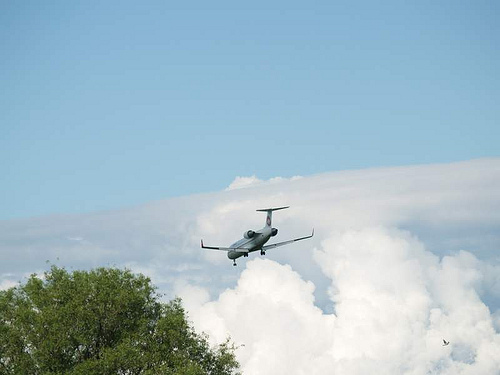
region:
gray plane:
[220, 186, 308, 278]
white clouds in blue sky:
[38, 23, 96, 70]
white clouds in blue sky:
[212, 69, 293, 133]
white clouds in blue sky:
[295, 21, 347, 95]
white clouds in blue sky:
[164, 68, 218, 120]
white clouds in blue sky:
[114, 106, 149, 141]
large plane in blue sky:
[196, 195, 318, 268]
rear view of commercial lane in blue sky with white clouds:
[197, 200, 320, 270]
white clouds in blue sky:
[15, 159, 497, 365]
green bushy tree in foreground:
[5, 257, 239, 368]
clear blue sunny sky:
[8, 0, 487, 221]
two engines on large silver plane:
[242, 226, 285, 241]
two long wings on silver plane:
[193, 226, 320, 252]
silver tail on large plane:
[255, 200, 292, 214]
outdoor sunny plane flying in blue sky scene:
[4, 5, 491, 364]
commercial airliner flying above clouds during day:
[197, 197, 320, 271]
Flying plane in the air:
[200, 203, 317, 268]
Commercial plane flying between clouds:
[192, 203, 319, 268]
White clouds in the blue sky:
[321, 225, 491, 327]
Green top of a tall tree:
[2, 266, 199, 373]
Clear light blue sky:
[154, 43, 375, 176]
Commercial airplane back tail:
[254, 202, 292, 224]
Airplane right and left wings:
[195, 230, 317, 255]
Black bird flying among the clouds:
[438, 336, 452, 349]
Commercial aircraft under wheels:
[221, 255, 245, 270]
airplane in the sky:
[189, 161, 329, 315]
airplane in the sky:
[179, 195, 322, 322]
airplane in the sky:
[174, 198, 316, 314]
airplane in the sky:
[196, 182, 323, 289]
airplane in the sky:
[179, 184, 335, 296]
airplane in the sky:
[181, 188, 327, 302]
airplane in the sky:
[186, 195, 326, 298]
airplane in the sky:
[170, 178, 340, 307]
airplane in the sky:
[188, 188, 335, 304]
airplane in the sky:
[200, 185, 327, 281]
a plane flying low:
[199, 204, 312, 266]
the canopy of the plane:
[244, 226, 261, 242]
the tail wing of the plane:
[252, 202, 289, 214]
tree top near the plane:
[0, 267, 245, 373]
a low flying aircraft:
[197, 204, 316, 269]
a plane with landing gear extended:
[198, 202, 321, 267]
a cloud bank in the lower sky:
[3, 157, 498, 372]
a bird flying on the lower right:
[435, 334, 455, 350]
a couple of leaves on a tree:
[226, 334, 232, 344]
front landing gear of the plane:
[229, 258, 239, 266]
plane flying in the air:
[197, 205, 316, 260]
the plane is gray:
[202, 204, 314, 271]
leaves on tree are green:
[2, 265, 231, 374]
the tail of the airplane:
[257, 203, 291, 225]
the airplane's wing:
[197, 236, 247, 253]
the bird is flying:
[438, 337, 453, 348]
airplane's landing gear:
[229, 254, 243, 268]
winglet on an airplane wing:
[196, 234, 206, 251]